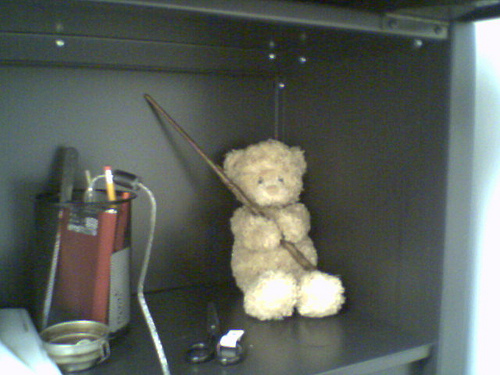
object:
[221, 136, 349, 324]
bear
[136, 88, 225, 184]
stick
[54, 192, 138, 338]
glass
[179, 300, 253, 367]
scissors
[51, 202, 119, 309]
notebook